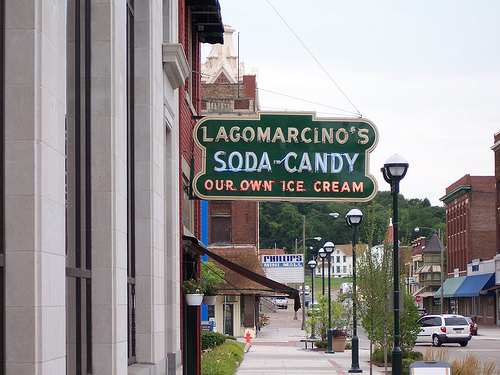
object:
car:
[414, 313, 478, 347]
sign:
[192, 111, 380, 203]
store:
[179, 1, 203, 372]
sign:
[262, 254, 305, 283]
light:
[380, 152, 410, 375]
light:
[346, 206, 363, 372]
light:
[318, 241, 335, 354]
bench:
[300, 337, 322, 350]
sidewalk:
[237, 312, 393, 374]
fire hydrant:
[244, 331, 253, 351]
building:
[439, 173, 500, 324]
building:
[0, 0, 259, 375]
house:
[315, 244, 369, 278]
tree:
[304, 201, 423, 373]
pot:
[184, 292, 217, 306]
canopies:
[434, 272, 497, 298]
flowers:
[185, 279, 215, 294]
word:
[262, 254, 304, 268]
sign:
[414, 293, 429, 306]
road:
[299, 293, 498, 372]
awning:
[177, 224, 301, 312]